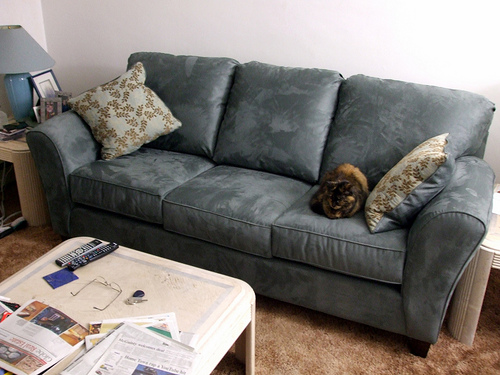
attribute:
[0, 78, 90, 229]
table — gray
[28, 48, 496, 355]
couch — blue gray, blue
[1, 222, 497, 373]
carpet — brown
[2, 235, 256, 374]
table — white,  WHITE , for  COFFEE, living room, small, plastic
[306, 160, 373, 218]
cat — tortoiseshell colored, orange , black 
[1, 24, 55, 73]
lampshade — blue , end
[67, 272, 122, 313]
eyeglasses — prescription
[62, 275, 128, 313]
glasses —  A PAIR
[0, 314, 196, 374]
newspaper — ON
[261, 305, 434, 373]
carpet — brown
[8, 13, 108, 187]
lamp — blue